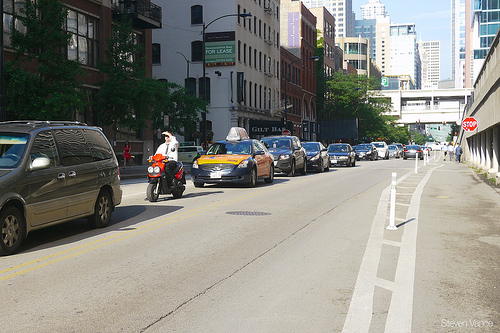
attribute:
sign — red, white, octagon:
[459, 115, 481, 135]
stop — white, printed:
[465, 120, 476, 128]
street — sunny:
[1, 136, 416, 260]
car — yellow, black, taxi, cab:
[189, 135, 278, 187]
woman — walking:
[123, 140, 135, 168]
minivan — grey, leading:
[2, 116, 123, 253]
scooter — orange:
[145, 151, 186, 196]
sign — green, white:
[202, 39, 240, 68]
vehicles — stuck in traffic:
[1, 118, 429, 205]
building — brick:
[283, 2, 319, 138]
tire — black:
[149, 178, 166, 203]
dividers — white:
[388, 144, 428, 237]